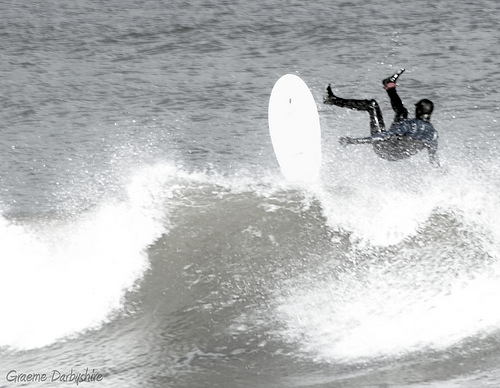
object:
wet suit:
[330, 86, 437, 161]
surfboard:
[266, 73, 320, 189]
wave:
[2, 156, 161, 347]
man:
[321, 67, 441, 167]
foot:
[380, 68, 405, 88]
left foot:
[323, 84, 334, 105]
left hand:
[337, 135, 350, 148]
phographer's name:
[4, 368, 101, 385]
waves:
[404, 1, 496, 82]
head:
[415, 99, 435, 120]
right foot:
[377, 68, 411, 86]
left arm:
[337, 122, 409, 147]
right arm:
[424, 140, 439, 168]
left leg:
[335, 98, 384, 137]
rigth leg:
[386, 86, 408, 121]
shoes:
[324, 83, 338, 106]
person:
[324, 68, 443, 169]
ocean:
[1, 2, 498, 387]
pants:
[337, 87, 407, 137]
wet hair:
[414, 98, 431, 116]